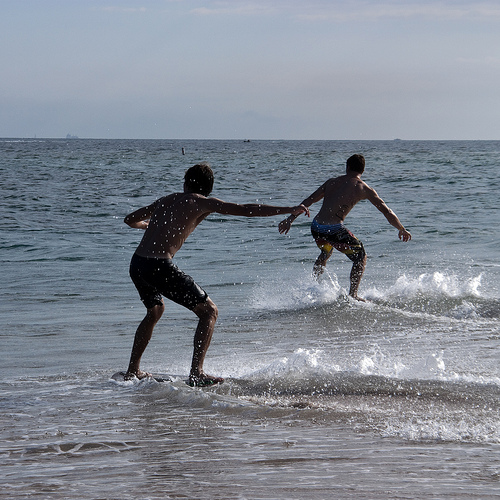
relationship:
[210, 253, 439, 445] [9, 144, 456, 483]
waves in ocean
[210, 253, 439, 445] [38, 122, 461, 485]
waves in ocean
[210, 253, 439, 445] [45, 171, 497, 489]
waves in ocean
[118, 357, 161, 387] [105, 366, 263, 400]
foot on surfboard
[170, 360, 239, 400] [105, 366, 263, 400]
foot on surfboard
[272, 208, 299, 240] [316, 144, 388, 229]
hand of a person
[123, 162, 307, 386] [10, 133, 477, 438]
male people in water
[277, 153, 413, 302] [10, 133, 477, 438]
person in water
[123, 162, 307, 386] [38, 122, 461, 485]
male people in middle of ocean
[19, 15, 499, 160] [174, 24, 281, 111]
sky covered of clouds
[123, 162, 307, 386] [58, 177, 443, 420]
male people surfing in ocean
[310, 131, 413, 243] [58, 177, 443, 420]
person surfing in ocean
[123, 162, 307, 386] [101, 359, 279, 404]
male people standing on surfboard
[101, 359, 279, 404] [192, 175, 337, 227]
surfboard with arms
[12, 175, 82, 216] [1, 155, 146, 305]
line in water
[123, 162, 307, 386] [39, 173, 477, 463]
male people surfing ocean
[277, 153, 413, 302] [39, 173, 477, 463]
person surfing ocean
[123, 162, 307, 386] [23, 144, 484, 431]
male people surfing ocean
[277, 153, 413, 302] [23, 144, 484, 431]
person surfing ocean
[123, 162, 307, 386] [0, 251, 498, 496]
male people surfing ocean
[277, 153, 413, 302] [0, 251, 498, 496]
person surfing ocean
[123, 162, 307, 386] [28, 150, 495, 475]
male people surfing ocean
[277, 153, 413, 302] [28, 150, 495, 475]
person surfing ocean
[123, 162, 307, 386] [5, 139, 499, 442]
male people surfing ocean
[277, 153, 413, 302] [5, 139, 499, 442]
person surfing ocean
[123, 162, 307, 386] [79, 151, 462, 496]
male people surfing ocean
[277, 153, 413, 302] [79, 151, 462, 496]
person surfing ocean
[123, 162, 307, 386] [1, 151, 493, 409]
male people surfing ocean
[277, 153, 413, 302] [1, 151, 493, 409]
person surfing ocean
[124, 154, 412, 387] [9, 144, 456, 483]
couple people surfing ocean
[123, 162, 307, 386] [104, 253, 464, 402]
male people surfing waves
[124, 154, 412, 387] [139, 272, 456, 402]
couple people surfing waves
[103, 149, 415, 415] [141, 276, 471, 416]
couple people surfing waves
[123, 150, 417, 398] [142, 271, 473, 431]
male people surfing waves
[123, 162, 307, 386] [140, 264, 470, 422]
male people surfing waves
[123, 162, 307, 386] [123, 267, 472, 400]
male people surfing waves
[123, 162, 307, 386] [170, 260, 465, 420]
male people surfing waves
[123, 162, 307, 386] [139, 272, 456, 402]
male people surfing waves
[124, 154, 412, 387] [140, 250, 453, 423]
couple people surfing waves